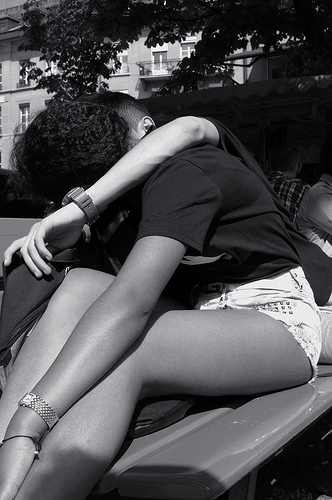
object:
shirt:
[109, 142, 301, 287]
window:
[21, 114, 27, 122]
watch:
[60, 185, 96, 216]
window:
[162, 51, 167, 62]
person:
[0, 90, 324, 498]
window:
[154, 55, 160, 67]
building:
[0, 0, 332, 172]